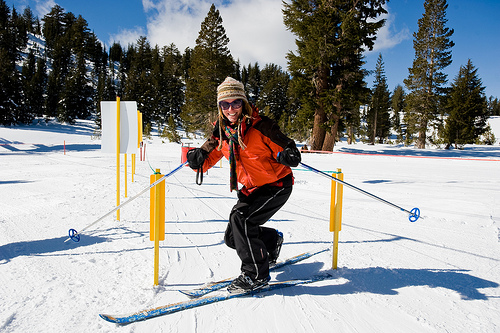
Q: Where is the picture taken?
A: Ski slope.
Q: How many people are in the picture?
A: One.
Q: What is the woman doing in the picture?
A: Skiing.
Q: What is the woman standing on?
A: Skis.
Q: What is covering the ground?
A: Snow.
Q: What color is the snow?
A: White.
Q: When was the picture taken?
A: Daytime.